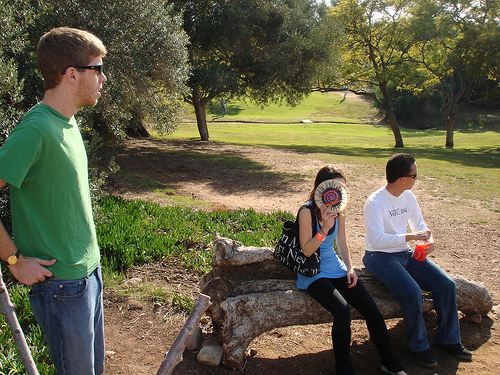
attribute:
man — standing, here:
[5, 24, 119, 371]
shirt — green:
[2, 106, 107, 281]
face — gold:
[9, 254, 19, 263]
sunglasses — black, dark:
[74, 60, 105, 76]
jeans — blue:
[27, 266, 111, 374]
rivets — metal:
[54, 278, 86, 300]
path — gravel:
[94, 129, 500, 374]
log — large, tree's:
[160, 218, 497, 369]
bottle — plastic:
[409, 236, 434, 264]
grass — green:
[89, 78, 500, 305]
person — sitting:
[267, 165, 415, 371]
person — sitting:
[363, 144, 478, 364]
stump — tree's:
[155, 224, 499, 374]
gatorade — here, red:
[409, 225, 433, 262]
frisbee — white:
[314, 180, 351, 213]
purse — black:
[273, 206, 323, 275]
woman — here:
[272, 163, 412, 368]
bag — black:
[271, 204, 322, 277]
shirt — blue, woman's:
[294, 205, 348, 291]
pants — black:
[312, 278, 403, 363]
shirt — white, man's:
[363, 190, 433, 254]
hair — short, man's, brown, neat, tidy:
[34, 23, 106, 87]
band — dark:
[6, 243, 23, 265]